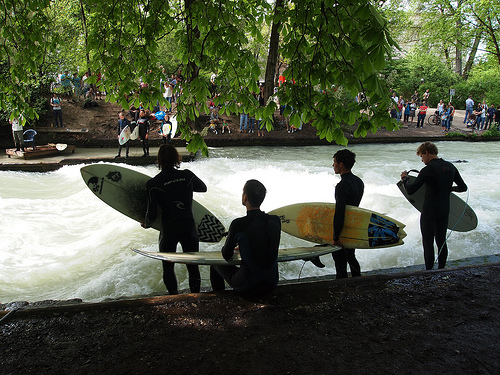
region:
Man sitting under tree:
[209, 179, 279, 304]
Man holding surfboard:
[332, 148, 364, 278]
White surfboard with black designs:
[81, 163, 224, 243]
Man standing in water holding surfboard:
[141, 142, 208, 292]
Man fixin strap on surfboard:
[396, 143, 467, 269]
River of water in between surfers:
[0, 143, 499, 303]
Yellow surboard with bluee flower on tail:
[264, 203, 407, 250]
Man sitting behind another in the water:
[208, 179, 282, 295]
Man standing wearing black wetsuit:
[331, 150, 365, 277]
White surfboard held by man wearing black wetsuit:
[396, 171, 476, 231]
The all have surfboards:
[90, 138, 468, 289]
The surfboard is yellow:
[292, 206, 368, 233]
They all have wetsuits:
[97, 134, 468, 301]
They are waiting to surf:
[95, 153, 467, 304]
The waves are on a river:
[3, 147, 490, 305]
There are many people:
[72, 57, 482, 194]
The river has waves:
[5, 141, 477, 300]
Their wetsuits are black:
[111, 134, 456, 326]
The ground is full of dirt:
[47, 280, 472, 374]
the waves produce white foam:
[17, 175, 257, 299]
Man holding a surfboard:
[398, 144, 483, 271]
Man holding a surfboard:
[265, 149, 405, 276]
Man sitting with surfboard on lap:
[130, 178, 343, 315]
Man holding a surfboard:
[73, 145, 223, 291]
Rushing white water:
[0, 137, 499, 307]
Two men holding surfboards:
[109, 107, 151, 159]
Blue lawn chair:
[19, 126, 44, 153]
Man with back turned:
[462, 93, 476, 123]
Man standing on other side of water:
[44, 88, 71, 130]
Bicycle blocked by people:
[425, 111, 455, 126]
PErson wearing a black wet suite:
[395, 129, 468, 282]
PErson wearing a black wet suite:
[294, 137, 394, 269]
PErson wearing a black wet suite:
[214, 181, 286, 319]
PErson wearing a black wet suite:
[133, 137, 208, 300]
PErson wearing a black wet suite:
[104, 103, 138, 159]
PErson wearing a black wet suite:
[132, 106, 167, 176]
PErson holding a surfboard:
[63, 117, 228, 313]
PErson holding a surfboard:
[207, 179, 289, 334]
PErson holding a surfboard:
[293, 142, 407, 293]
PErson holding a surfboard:
[385, 119, 497, 292]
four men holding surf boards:
[86, 107, 484, 291]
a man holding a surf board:
[120, 131, 210, 300]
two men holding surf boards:
[107, 102, 179, 146]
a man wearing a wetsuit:
[135, 147, 207, 267]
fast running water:
[23, 146, 308, 261]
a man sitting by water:
[196, 177, 288, 300]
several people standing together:
[369, 89, 489, 141]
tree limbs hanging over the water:
[6, 20, 409, 165]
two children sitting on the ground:
[198, 118, 232, 138]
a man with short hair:
[234, 172, 278, 214]